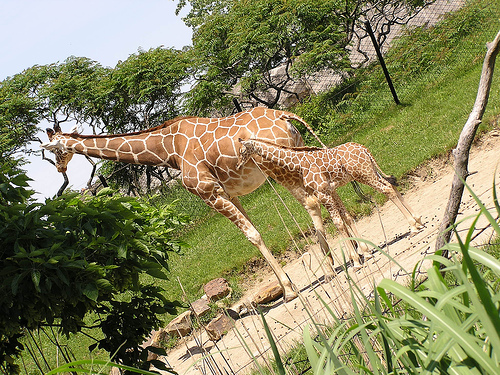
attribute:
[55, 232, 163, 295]
leaves — green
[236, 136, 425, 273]
giraffe — young, orange, white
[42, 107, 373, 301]
giraffe — adult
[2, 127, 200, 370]
tree — green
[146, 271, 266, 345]
rocks — light brown gray and yellow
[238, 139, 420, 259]
giraffe — smallest, baby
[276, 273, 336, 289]
feet — giraffes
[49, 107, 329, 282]
giraffe — mother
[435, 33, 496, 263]
stick — long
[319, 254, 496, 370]
grass — tall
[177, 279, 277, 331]
rocks — large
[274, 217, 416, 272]
feet — giraffes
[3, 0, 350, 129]
trees — tall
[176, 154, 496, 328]
patch — dirt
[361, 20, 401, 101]
post — black, fencing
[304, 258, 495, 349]
grass — tall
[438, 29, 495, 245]
stick — long